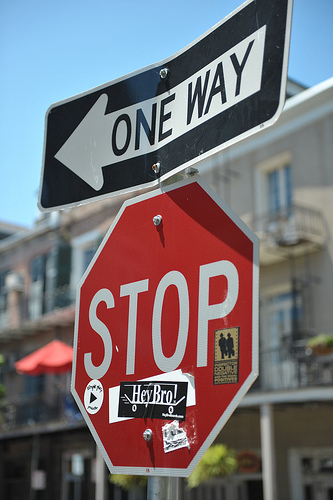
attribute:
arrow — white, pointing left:
[56, 98, 281, 163]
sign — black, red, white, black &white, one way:
[26, 28, 314, 211]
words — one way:
[119, 112, 257, 127]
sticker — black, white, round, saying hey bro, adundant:
[112, 377, 193, 417]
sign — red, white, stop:
[60, 198, 265, 427]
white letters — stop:
[94, 291, 230, 346]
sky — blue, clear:
[162, 23, 205, 35]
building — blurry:
[300, 91, 332, 139]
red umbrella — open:
[15, 337, 88, 373]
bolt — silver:
[146, 210, 188, 231]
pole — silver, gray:
[145, 475, 179, 492]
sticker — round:
[63, 369, 110, 428]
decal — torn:
[162, 432, 218, 457]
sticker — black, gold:
[215, 331, 248, 385]